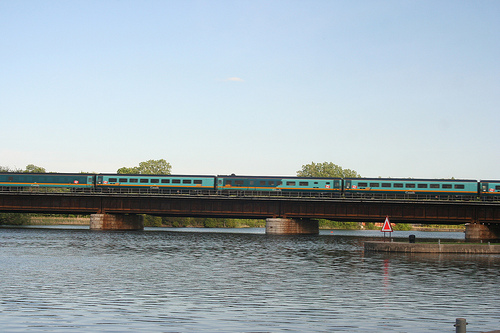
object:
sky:
[0, 0, 500, 180]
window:
[299, 180, 309, 187]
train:
[0, 170, 500, 202]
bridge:
[0, 180, 500, 238]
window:
[356, 182, 368, 187]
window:
[368, 183, 380, 188]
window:
[453, 185, 465, 188]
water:
[0, 223, 500, 332]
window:
[392, 182, 404, 188]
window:
[428, 183, 440, 189]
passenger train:
[0, 171, 500, 203]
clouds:
[0, 0, 499, 181]